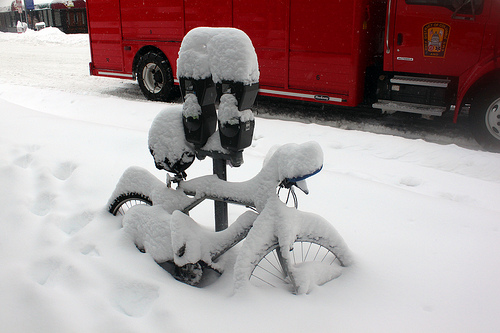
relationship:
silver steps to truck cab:
[370, 99, 446, 119] [372, 1, 499, 123]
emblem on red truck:
[423, 22, 448, 58] [83, 0, 499, 155]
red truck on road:
[80, 0, 498, 157] [0, 33, 498, 333]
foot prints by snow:
[3, 147, 159, 318] [1, 81, 498, 328]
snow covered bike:
[109, 112, 352, 295] [102, 114, 357, 299]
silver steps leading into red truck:
[370, 69, 458, 133] [83, 0, 499, 155]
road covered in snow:
[374, 174, 441, 259] [340, 226, 462, 305]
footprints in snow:
[119, 276, 152, 318] [28, 175, 66, 220]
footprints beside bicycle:
[119, 276, 152, 318] [104, 105, 356, 295]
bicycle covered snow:
[104, 123, 354, 293] [180, 228, 276, 272]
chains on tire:
[115, 59, 169, 99] [129, 43, 176, 103]